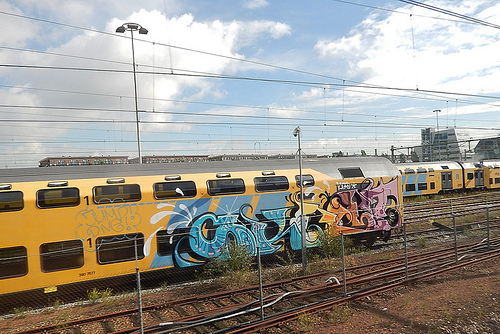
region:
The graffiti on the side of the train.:
[147, 175, 406, 267]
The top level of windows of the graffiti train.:
[1, 176, 323, 199]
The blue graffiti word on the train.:
[165, 205, 305, 254]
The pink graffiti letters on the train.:
[340, 181, 398, 232]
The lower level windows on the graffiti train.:
[4, 211, 389, 286]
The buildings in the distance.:
[42, 124, 499, 163]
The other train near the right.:
[392, 163, 498, 190]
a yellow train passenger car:
[0, 155, 401, 306]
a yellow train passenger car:
[394, 162, 462, 195]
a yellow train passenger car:
[459, 158, 499, 190]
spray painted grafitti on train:
[146, 172, 402, 267]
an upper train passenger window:
[0, 189, 25, 211]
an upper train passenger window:
[36, 185, 80, 207]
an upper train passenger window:
[92, 183, 140, 202]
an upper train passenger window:
[153, 180, 195, 198]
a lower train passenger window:
[1, 245, 28, 278]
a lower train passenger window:
[39, 239, 84, 272]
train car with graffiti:
[3, 153, 411, 312]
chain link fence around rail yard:
[8, 200, 498, 332]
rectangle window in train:
[34, 184, 84, 209]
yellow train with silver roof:
[4, 153, 411, 303]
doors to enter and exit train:
[440, 166, 454, 193]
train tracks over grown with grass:
[402, 191, 498, 238]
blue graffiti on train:
[174, 206, 323, 270]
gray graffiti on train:
[73, 199, 144, 256]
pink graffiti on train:
[362, 174, 400, 231]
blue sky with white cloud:
[2, 67, 498, 157]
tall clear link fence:
[152, 232, 242, 304]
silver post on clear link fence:
[249, 236, 286, 317]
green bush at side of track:
[76, 280, 128, 305]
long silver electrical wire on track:
[184, 290, 298, 320]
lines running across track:
[143, 296, 234, 332]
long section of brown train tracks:
[206, 243, 441, 302]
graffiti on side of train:
[170, 187, 385, 256]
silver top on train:
[115, 158, 173, 176]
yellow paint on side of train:
[24, 209, 77, 234]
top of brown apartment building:
[43, 143, 146, 164]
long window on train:
[26, 181, 88, 214]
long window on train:
[85, 181, 149, 209]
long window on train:
[149, 175, 204, 202]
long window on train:
[208, 176, 247, 202]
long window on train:
[251, 176, 291, 198]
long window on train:
[3, 244, 29, 281]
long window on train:
[33, 243, 90, 275]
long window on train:
[96, 231, 153, 267]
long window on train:
[156, 224, 206, 269]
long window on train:
[258, 206, 306, 244]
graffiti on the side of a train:
[75, 175, 404, 265]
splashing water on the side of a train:
[136, 187, 202, 254]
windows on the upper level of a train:
[1, 175, 315, 214]